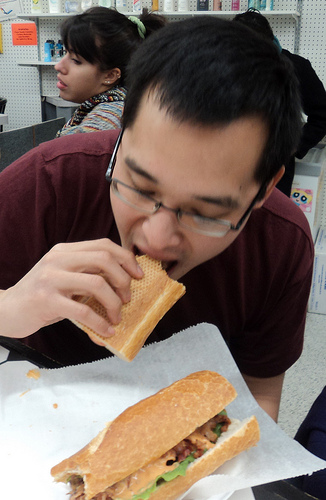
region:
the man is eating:
[10, 80, 323, 433]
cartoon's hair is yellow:
[275, 180, 324, 214]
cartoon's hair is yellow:
[290, 185, 316, 226]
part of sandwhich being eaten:
[89, 269, 178, 350]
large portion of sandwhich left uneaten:
[52, 409, 258, 484]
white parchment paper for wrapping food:
[44, 355, 166, 389]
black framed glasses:
[96, 180, 248, 237]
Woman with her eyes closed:
[58, 19, 126, 91]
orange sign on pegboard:
[11, 25, 48, 47]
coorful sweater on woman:
[50, 107, 118, 131]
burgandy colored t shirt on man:
[16, 159, 79, 213]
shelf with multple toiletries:
[82, 0, 287, 11]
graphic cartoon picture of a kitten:
[287, 176, 313, 219]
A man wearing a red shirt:
[13, 35, 306, 361]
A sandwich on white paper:
[50, 379, 260, 494]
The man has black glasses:
[100, 39, 279, 297]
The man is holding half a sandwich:
[21, 200, 212, 354]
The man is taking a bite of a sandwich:
[36, 51, 279, 381]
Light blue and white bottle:
[241, 0, 297, 15]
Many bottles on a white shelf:
[36, 1, 276, 11]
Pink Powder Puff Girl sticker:
[290, 184, 313, 217]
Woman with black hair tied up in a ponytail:
[47, 8, 158, 143]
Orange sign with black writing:
[7, 19, 44, 51]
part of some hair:
[176, 53, 209, 99]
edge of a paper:
[252, 467, 280, 489]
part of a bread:
[123, 445, 149, 470]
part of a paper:
[62, 406, 89, 435]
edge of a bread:
[116, 458, 138, 476]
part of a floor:
[284, 402, 301, 436]